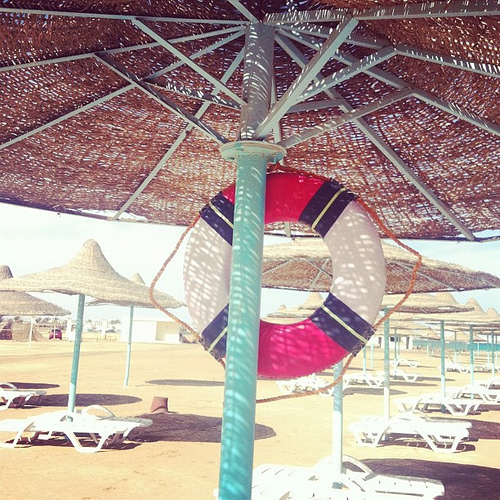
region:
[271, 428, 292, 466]
part of a ground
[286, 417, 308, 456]
part of a ground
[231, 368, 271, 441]
part f a pst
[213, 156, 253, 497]
the stand is green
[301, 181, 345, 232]
the colour is black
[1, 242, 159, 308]
the umbrella is gray in colour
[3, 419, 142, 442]
the busking beds are white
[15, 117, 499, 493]
the photo is taken in the beach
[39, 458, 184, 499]
the sand is brown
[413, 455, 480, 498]
the shadow is on the ground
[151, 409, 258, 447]
the shadow is on the ground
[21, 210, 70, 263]
this is the sky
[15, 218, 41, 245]
the sky is blue in color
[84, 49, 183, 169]
this is a umbrella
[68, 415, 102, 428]
this is a bed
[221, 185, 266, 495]
this is a pole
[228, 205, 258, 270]
the pole is blue in color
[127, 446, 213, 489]
this is the ground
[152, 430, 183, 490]
the ground is brown in color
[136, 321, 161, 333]
this is a wall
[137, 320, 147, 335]
the wall is white in color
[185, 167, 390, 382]
the wreath on pole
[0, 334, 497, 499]
the white seating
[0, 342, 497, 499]
the sandy beach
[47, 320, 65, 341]
a red jeep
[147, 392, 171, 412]
a barrel next to lounge chair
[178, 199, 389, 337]
the white on the wreath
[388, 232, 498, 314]
the cloudy part of the sky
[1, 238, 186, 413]
beach umbrella on blue pole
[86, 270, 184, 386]
beach umbrella on blue pole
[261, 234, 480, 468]
beach umbrella on blue pole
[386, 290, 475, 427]
beach umbrella on blue pole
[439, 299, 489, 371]
beach umbrella on blue pole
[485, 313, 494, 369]
beach umbrella on blue pole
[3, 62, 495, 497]
Umbrellas and beach chairs on the beach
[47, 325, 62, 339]
Red car in the background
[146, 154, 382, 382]
life saver on the pole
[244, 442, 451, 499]
lounge chair on the beach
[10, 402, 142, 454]
lounge chair on the beach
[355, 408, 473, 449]
lounge chair on the beach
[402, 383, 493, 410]
lounge chair on the beach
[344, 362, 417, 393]
lounge chair on the beach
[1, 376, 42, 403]
lounge chair on the beach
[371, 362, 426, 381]
lounge chair on the beach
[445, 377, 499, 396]
lounge chair on the beach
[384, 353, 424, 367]
lounge chair on the beach